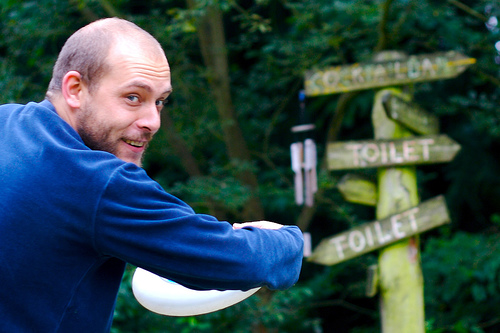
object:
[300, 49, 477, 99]
sign is wooden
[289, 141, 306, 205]
chime is still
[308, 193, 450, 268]
word is on sign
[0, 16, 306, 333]
man is throwing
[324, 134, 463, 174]
sign is on post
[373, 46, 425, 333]
post is wooden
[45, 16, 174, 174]
head is bald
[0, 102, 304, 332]
shirt is blue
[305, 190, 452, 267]
sign is on post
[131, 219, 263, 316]
tray is white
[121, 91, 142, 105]
man has eye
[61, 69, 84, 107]
man has ear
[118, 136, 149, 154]
man has mouth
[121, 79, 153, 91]
man has eyebrow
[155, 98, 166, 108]
eye is blue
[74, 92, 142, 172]
man has beard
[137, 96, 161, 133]
man has nose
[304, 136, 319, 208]
chime is hanging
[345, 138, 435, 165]
word is white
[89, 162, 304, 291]
sleeve is long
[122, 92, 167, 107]
eyes are blue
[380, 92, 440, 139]
arrow is wooden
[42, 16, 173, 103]
hair is balding